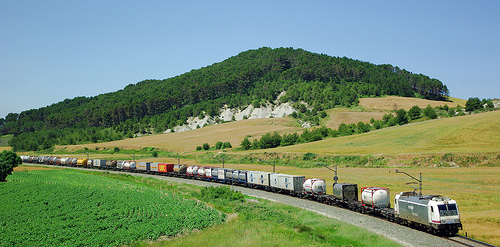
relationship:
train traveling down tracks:
[13, 155, 461, 239] [20, 160, 492, 245]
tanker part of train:
[300, 176, 328, 201] [10, 143, 466, 237]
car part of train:
[357, 187, 389, 210] [10, 143, 466, 237]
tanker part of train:
[185, 161, 225, 184] [10, 143, 466, 237]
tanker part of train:
[114, 159, 144, 176] [10, 143, 466, 237]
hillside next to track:
[34, 90, 484, 244] [447, 230, 493, 242]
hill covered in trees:
[2, 43, 498, 243] [63, 46, 440, 134]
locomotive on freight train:
[397, 188, 462, 238] [18, 146, 463, 240]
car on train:
[361, 180, 390, 210] [17, 138, 448, 225]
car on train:
[172, 158, 212, 180] [18, 152, 460, 235]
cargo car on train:
[271, 170, 305, 195] [18, 152, 460, 235]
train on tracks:
[10, 143, 466, 237] [329, 204, 499, 245]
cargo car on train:
[242, 162, 269, 189] [57, 147, 464, 227]